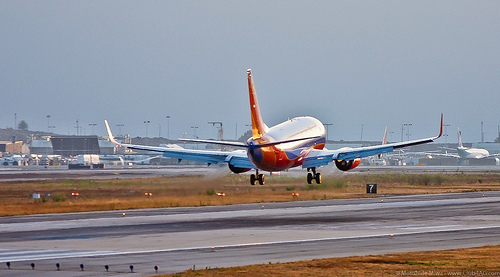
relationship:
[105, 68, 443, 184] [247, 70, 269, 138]
plane has tail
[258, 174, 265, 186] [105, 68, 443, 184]
wheel below plane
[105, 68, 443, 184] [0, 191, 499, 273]
plane above runway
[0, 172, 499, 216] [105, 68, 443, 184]
field under plane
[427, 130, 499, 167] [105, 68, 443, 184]
plane right of plane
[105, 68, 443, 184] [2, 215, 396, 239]
plane casting shadow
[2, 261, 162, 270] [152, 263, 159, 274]
line has light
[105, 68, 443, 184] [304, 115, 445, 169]
plane has wing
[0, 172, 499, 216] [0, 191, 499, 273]
field above runway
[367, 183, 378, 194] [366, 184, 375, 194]
sign has 7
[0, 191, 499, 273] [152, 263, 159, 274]
runway has light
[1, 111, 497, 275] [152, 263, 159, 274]
airport has light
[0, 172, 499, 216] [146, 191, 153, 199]
field has light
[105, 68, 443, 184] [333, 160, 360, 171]
plane has engine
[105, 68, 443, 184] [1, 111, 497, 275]
plane inside of airport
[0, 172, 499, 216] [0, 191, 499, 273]
field on side of runway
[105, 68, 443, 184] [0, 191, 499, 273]
plane on top of runway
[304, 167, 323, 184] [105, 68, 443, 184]
landing gear below plane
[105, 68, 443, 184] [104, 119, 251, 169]
plane has wing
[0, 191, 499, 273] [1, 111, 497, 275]
runway inside of airport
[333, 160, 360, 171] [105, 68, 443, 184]
engine below plane